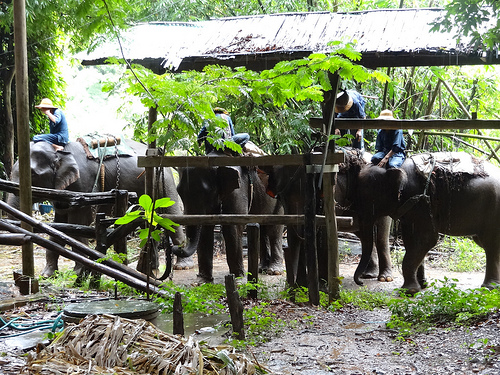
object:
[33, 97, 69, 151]
man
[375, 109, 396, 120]
hat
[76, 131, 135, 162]
pack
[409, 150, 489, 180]
pack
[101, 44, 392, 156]
plants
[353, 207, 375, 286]
trunk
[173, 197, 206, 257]
trunk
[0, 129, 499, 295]
elephants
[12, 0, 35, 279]
pole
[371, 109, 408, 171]
workers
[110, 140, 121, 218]
metal chain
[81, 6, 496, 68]
roof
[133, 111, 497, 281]
fencing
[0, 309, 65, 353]
hose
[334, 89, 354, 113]
hat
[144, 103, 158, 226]
post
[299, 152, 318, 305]
post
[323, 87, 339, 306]
post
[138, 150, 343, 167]
post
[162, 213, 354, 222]
post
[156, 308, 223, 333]
puddle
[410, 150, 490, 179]
blanket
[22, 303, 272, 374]
haystack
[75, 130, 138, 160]
saddle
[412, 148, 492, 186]
saddle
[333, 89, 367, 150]
man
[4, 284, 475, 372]
ground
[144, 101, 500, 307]
pen